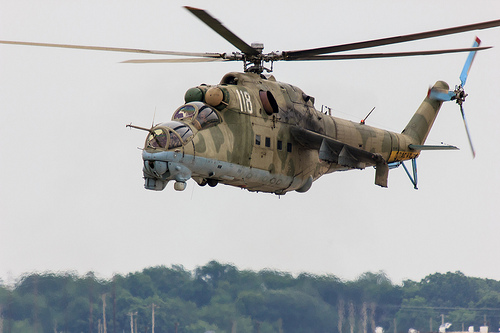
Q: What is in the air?
A: Helicopter.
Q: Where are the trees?
A: In background.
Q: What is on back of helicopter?
A: Rear propeller.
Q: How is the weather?
A: Clear.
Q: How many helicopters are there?
A: One.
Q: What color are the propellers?
A: Black.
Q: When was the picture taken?
A: Daytime.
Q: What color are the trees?
A: Green.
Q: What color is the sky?
A: Gray.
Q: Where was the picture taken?
A: The sky.